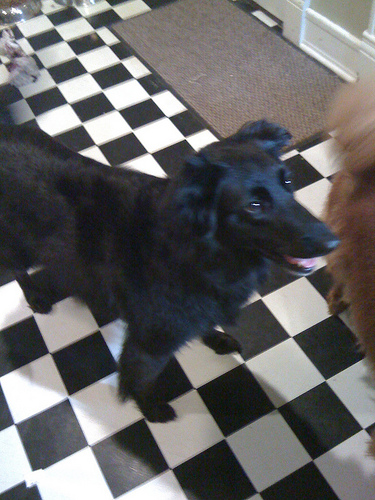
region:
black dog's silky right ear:
[165, 158, 236, 242]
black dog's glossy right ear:
[167, 149, 229, 242]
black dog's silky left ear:
[238, 117, 299, 162]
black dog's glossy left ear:
[239, 117, 294, 154]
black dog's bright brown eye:
[233, 189, 272, 223]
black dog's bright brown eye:
[282, 173, 298, 197]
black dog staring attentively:
[9, 98, 336, 425]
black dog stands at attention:
[7, 105, 341, 419]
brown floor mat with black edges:
[111, 1, 368, 156]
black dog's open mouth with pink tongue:
[281, 213, 341, 285]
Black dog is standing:
[0, 114, 333, 424]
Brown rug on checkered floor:
[103, 0, 346, 158]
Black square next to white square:
[89, 418, 171, 498]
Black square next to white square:
[192, 362, 276, 436]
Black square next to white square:
[276, 380, 362, 459]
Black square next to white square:
[49, 327, 118, 397]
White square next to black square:
[72, 369, 142, 443]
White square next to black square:
[144, 386, 222, 467]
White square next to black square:
[226, 410, 309, 489]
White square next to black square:
[261, 277, 334, 337]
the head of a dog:
[185, 128, 348, 285]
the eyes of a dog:
[212, 147, 309, 229]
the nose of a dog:
[283, 210, 344, 282]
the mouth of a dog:
[255, 205, 349, 282]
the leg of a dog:
[99, 283, 227, 448]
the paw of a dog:
[140, 391, 186, 432]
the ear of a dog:
[168, 147, 260, 271]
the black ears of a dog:
[185, 104, 294, 272]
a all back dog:
[52, 99, 348, 364]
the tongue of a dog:
[266, 242, 328, 296]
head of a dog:
[166, 109, 342, 280]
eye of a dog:
[247, 158, 299, 221]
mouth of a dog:
[260, 201, 340, 281]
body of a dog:
[14, 140, 221, 324]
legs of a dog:
[131, 303, 246, 427]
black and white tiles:
[17, 399, 179, 498]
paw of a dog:
[104, 348, 187, 431]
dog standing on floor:
[5, 96, 337, 441]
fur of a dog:
[49, 161, 144, 261]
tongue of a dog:
[282, 253, 322, 271]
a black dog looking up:
[2, 118, 336, 420]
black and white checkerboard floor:
[2, 4, 373, 495]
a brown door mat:
[112, 5, 361, 160]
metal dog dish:
[1, 0, 41, 20]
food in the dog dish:
[2, 0, 25, 7]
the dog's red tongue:
[289, 255, 319, 266]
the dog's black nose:
[316, 235, 337, 252]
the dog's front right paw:
[140, 391, 176, 423]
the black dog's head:
[169, 114, 337, 273]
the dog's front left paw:
[207, 330, 241, 354]